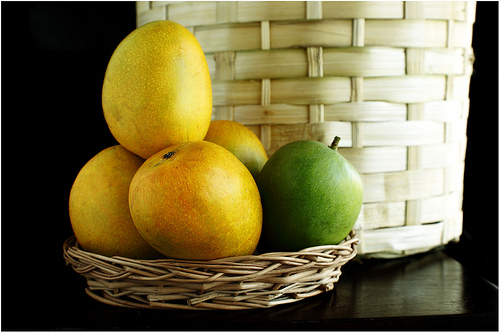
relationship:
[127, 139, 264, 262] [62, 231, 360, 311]
mango in basket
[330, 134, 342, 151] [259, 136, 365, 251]
stem on mango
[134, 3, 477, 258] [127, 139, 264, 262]
basket behind mango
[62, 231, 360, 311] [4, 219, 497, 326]
basket on table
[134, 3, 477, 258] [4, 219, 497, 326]
basket on table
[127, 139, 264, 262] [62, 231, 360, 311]
mango on tray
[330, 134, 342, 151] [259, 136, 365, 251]
stem of food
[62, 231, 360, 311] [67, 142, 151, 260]
basket under fruit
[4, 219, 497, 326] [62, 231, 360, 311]
table under basket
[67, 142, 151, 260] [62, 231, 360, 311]
fruit on trays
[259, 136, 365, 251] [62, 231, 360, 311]
fruit on tray